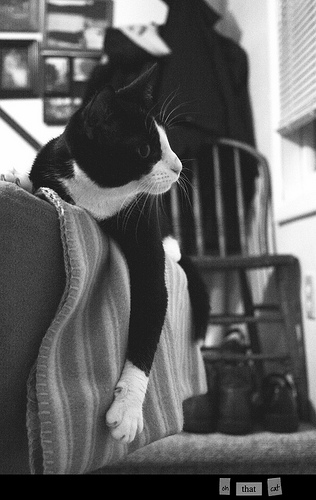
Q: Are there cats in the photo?
A: Yes, there is a cat.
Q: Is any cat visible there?
A: Yes, there is a cat.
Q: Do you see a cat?
A: Yes, there is a cat.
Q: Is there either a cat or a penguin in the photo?
A: Yes, there is a cat.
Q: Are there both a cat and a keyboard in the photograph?
A: No, there is a cat but no keyboards.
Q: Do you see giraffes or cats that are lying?
A: Yes, the cat is lying.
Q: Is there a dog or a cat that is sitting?
A: Yes, the cat is sitting.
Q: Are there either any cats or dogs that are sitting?
A: Yes, the cat is sitting.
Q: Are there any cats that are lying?
A: Yes, there is a cat that is lying.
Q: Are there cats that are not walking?
A: Yes, there is a cat that is lying.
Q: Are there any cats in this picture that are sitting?
A: Yes, there is a cat that is sitting.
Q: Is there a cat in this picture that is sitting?
A: Yes, there is a cat that is sitting.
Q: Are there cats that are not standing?
A: Yes, there is a cat that is sitting.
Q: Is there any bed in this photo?
A: No, there are no beds.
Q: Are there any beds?
A: No, there are no beds.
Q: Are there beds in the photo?
A: No, there are no beds.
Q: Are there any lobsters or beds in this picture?
A: No, there are no beds or lobsters.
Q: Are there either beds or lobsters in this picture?
A: No, there are no beds or lobsters.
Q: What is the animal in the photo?
A: The animal is a cat.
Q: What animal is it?
A: The animal is a cat.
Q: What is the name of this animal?
A: This is a cat.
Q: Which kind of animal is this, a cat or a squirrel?
A: This is a cat.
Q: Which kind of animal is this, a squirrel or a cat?
A: This is a cat.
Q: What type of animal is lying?
A: The animal is a cat.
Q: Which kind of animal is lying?
A: The animal is a cat.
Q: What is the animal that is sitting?
A: The animal is a cat.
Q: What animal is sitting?
A: The animal is a cat.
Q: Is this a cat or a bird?
A: This is a cat.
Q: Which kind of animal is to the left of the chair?
A: The animal is a cat.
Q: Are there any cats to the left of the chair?
A: Yes, there is a cat to the left of the chair.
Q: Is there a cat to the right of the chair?
A: No, the cat is to the left of the chair.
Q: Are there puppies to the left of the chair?
A: No, there is a cat to the left of the chair.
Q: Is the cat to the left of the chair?
A: Yes, the cat is to the left of the chair.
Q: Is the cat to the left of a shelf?
A: No, the cat is to the left of the chair.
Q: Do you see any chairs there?
A: Yes, there is a chair.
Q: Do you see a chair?
A: Yes, there is a chair.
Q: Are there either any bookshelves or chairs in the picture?
A: Yes, there is a chair.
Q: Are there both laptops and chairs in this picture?
A: No, there is a chair but no laptops.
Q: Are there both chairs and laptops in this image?
A: No, there is a chair but no laptops.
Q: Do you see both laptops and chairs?
A: No, there is a chair but no laptops.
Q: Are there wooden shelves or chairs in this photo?
A: Yes, there is a wood chair.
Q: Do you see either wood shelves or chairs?
A: Yes, there is a wood chair.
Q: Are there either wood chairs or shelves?
A: Yes, there is a wood chair.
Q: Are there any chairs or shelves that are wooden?
A: Yes, the chair is wooden.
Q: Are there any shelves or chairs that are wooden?
A: Yes, the chair is wooden.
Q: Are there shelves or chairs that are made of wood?
A: Yes, the chair is made of wood.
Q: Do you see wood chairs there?
A: Yes, there is a wood chair.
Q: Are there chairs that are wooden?
A: Yes, there is a chair that is wooden.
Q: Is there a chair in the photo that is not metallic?
A: Yes, there is a wooden chair.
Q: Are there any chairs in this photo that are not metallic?
A: Yes, there is a wooden chair.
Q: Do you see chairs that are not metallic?
A: Yes, there is a wooden chair.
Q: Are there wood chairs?
A: Yes, there is a chair that is made of wood.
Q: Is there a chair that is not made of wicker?
A: Yes, there is a chair that is made of wood.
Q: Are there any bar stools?
A: No, there are no bar stools.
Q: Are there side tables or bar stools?
A: No, there are no bar stools or side tables.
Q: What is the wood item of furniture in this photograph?
A: The piece of furniture is a chair.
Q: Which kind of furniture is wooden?
A: The furniture is a chair.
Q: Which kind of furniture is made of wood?
A: The furniture is a chair.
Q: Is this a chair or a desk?
A: This is a chair.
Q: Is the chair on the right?
A: Yes, the chair is on the right of the image.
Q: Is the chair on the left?
A: No, the chair is on the right of the image.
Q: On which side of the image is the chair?
A: The chair is on the right of the image.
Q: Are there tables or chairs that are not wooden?
A: No, there is a chair but it is wooden.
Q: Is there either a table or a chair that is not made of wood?
A: No, there is a chair but it is made of wood.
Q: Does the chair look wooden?
A: Yes, the chair is wooden.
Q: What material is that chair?
A: The chair is made of wood.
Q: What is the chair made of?
A: The chair is made of wood.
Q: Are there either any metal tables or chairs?
A: No, there is a chair but it is wooden.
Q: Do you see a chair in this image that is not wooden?
A: No, there is a chair but it is wooden.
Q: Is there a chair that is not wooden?
A: No, there is a chair but it is wooden.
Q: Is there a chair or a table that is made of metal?
A: No, there is a chair but it is made of wood.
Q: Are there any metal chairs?
A: No, there is a chair but it is made of wood.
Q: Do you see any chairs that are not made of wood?
A: No, there is a chair but it is made of wood.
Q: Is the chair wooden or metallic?
A: The chair is wooden.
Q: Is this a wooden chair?
A: Yes, this is a wooden chair.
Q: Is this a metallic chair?
A: No, this is a wooden chair.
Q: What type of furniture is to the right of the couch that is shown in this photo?
A: The piece of furniture is a chair.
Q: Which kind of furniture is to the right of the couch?
A: The piece of furniture is a chair.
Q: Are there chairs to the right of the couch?
A: Yes, there is a chair to the right of the couch.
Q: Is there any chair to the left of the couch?
A: No, the chair is to the right of the couch.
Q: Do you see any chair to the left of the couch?
A: No, the chair is to the right of the couch.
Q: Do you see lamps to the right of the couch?
A: No, there is a chair to the right of the couch.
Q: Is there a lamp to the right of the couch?
A: No, there is a chair to the right of the couch.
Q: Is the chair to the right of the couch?
A: Yes, the chair is to the right of the couch.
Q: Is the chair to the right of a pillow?
A: No, the chair is to the right of the couch.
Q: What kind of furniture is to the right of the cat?
A: The piece of furniture is a chair.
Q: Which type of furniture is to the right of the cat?
A: The piece of furniture is a chair.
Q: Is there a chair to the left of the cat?
A: No, the chair is to the right of the cat.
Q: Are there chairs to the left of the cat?
A: No, the chair is to the right of the cat.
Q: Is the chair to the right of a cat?
A: Yes, the chair is to the right of a cat.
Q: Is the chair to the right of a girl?
A: No, the chair is to the right of a cat.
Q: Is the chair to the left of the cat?
A: No, the chair is to the right of the cat.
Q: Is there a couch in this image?
A: Yes, there is a couch.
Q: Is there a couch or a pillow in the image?
A: Yes, there is a couch.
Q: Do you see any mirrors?
A: No, there are no mirrors.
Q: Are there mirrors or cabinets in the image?
A: No, there are no mirrors or cabinets.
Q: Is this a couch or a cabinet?
A: This is a couch.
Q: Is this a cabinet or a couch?
A: This is a couch.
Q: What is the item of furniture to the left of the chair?
A: The piece of furniture is a couch.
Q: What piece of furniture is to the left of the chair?
A: The piece of furniture is a couch.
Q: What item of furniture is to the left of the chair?
A: The piece of furniture is a couch.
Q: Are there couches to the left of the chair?
A: Yes, there is a couch to the left of the chair.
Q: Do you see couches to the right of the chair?
A: No, the couch is to the left of the chair.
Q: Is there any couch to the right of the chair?
A: No, the couch is to the left of the chair.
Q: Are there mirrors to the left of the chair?
A: No, there is a couch to the left of the chair.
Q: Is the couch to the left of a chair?
A: Yes, the couch is to the left of a chair.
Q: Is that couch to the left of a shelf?
A: No, the couch is to the left of a chair.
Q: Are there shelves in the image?
A: No, there are no shelves.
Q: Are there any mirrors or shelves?
A: No, there are no shelves or mirrors.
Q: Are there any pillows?
A: No, there are no pillows.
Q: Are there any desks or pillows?
A: No, there are no pillows or desks.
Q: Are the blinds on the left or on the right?
A: The blinds are on the right of the image.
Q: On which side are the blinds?
A: The blinds are on the right of the image.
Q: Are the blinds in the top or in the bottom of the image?
A: The blinds are in the top of the image.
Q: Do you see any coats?
A: Yes, there is a coat.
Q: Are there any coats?
A: Yes, there is a coat.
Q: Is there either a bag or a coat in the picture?
A: Yes, there is a coat.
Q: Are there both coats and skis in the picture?
A: No, there is a coat but no skis.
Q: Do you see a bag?
A: No, there are no bags.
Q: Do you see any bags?
A: No, there are no bags.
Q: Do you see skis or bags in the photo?
A: No, there are no bags or skis.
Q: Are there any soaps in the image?
A: No, there are no soaps.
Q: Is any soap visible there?
A: No, there are no soaps.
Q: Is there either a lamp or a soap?
A: No, there are no soaps or lamps.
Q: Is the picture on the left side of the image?
A: Yes, the picture is on the left of the image.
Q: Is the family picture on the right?
A: No, the picture is on the left of the image.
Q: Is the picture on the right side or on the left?
A: The picture is on the left of the image.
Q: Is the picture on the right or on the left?
A: The picture is on the left of the image.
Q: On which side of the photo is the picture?
A: The picture is on the left of the image.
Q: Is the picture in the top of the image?
A: Yes, the picture is in the top of the image.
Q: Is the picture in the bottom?
A: No, the picture is in the top of the image.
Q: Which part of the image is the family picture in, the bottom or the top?
A: The picture is in the top of the image.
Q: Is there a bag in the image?
A: No, there are no bags.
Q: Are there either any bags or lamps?
A: No, there are no bags or lamps.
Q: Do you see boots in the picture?
A: Yes, there are boots.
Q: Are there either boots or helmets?
A: Yes, there are boots.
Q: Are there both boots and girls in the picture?
A: No, there are boots but no girls.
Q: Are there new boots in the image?
A: Yes, there are new boots.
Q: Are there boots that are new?
A: Yes, there are boots that are new.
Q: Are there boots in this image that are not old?
A: Yes, there are new boots.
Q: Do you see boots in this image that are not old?
A: Yes, there are new boots.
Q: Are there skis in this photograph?
A: No, there are no skis.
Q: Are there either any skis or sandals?
A: No, there are no skis or sandals.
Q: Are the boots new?
A: Yes, the boots are new.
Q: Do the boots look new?
A: Yes, the boots are new.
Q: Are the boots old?
A: No, the boots are new.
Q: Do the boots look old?
A: No, the boots are new.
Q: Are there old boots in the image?
A: No, there are boots but they are new.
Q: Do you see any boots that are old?
A: No, there are boots but they are new.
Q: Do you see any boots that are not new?
A: No, there are boots but they are new.